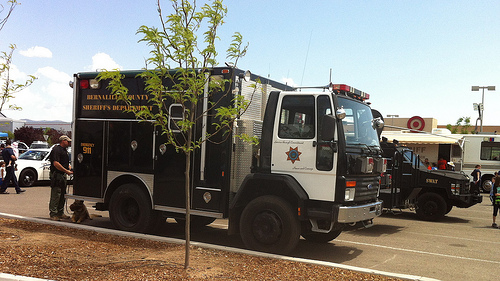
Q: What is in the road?
A: Truck.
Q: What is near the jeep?
A: Truck.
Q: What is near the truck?
A: Flower.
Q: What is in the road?
A: Truck.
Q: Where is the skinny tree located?
A: On the island.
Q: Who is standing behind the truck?
A: Police officers.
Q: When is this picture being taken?
A: Daytime.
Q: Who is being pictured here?
A: Police.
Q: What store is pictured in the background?
A: Target.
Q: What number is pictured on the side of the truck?
A: 911.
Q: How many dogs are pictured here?
A: One.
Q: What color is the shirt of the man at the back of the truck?
A: Black.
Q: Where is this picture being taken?
A: A Parking Lot.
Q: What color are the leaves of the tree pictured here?
A: Green.